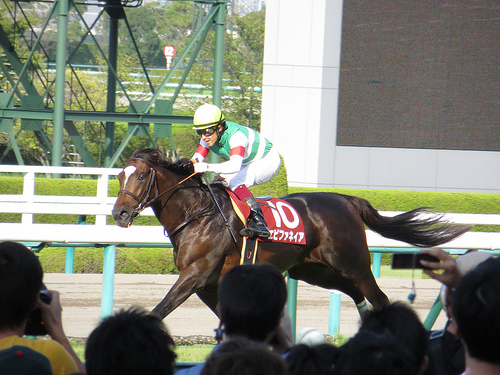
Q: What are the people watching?
A: Horse Race.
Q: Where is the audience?
A: In the stadium.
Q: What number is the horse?
A: 10.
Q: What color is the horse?
A: Brown.